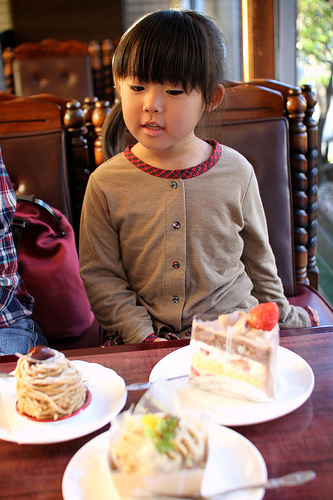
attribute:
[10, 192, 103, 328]
purse — maroon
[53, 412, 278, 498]
plate — white, ceramic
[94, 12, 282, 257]
girl — young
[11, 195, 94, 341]
bag — red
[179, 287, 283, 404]
cake — sliced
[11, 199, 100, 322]
bag — canvas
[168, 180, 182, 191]
button — round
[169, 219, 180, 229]
button — round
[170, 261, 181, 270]
button — round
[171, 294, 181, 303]
button — round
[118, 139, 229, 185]
trim — plaid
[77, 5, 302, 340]
girl — looking, little, sitting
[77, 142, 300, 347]
shirt — brown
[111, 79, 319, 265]
chair — burgundy, leather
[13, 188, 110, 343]
bag — red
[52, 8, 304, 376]
girl — looking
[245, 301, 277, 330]
strawberry — red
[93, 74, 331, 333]
chairs — empty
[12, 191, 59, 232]
handle — wooden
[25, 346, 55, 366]
plum — wrapped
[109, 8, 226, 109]
hair — dark, black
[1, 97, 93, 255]
chair — brown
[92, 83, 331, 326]
chair — brown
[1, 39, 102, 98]
chair — brown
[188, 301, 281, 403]
cake — triangular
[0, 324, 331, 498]
table — brown, wooden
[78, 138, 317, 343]
shirt — tan, plaid